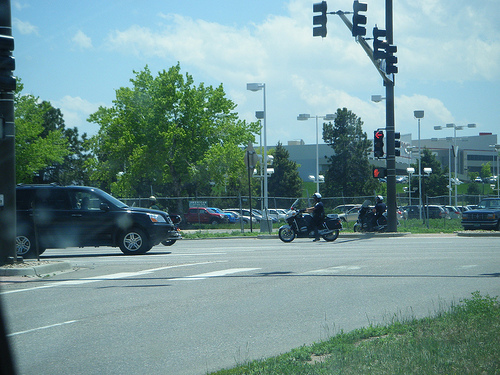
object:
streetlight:
[372, 130, 384, 159]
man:
[364, 193, 387, 230]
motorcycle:
[353, 199, 400, 233]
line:
[1, 256, 231, 298]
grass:
[191, 291, 499, 374]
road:
[1, 238, 499, 374]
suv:
[13, 183, 186, 258]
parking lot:
[160, 200, 495, 228]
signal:
[372, 167, 384, 179]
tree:
[80, 61, 262, 230]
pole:
[261, 83, 271, 219]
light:
[245, 81, 266, 92]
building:
[123, 134, 500, 208]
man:
[304, 190, 326, 242]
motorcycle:
[277, 195, 346, 243]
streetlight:
[311, 1, 330, 39]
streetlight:
[351, 0, 369, 39]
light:
[370, 92, 384, 104]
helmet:
[375, 194, 385, 202]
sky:
[14, 2, 500, 157]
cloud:
[71, 29, 92, 52]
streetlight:
[394, 130, 402, 157]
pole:
[384, 1, 400, 233]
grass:
[176, 218, 466, 241]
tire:
[12, 226, 38, 261]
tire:
[116, 222, 152, 257]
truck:
[459, 196, 499, 234]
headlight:
[485, 212, 496, 219]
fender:
[459, 220, 499, 230]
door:
[70, 186, 118, 245]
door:
[27, 187, 71, 246]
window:
[73, 188, 111, 210]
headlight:
[147, 210, 168, 226]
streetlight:
[371, 23, 390, 65]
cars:
[182, 206, 225, 225]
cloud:
[13, 18, 38, 38]